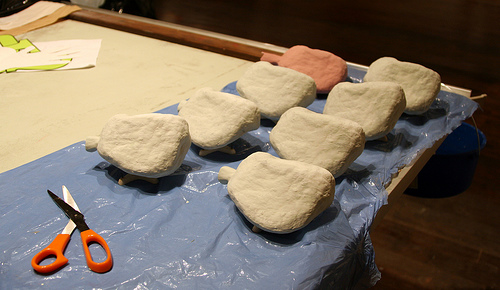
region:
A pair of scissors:
[21, 145, 102, 273]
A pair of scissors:
[80, 190, 155, 272]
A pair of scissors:
[55, 167, 126, 281]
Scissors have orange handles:
[26, 228, 120, 275]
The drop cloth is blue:
[1, 57, 478, 287]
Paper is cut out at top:
[0, 31, 100, 72]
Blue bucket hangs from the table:
[401, 116, 483, 210]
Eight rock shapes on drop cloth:
[76, 46, 445, 238]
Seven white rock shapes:
[78, 42, 445, 241]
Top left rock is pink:
[261, 38, 353, 100]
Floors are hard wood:
[129, 3, 498, 289]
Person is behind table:
[1, 0, 186, 48]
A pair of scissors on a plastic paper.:
[6, 176, 138, 288]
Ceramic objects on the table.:
[105, 93, 359, 225]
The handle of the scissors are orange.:
[18, 238, 120, 289]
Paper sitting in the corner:
[13, 31, 122, 94]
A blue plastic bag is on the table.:
[48, 141, 274, 288]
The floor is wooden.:
[393, 218, 497, 286]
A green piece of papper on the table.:
[1, 27, 73, 103]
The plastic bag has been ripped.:
[346, 101, 447, 268]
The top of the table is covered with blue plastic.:
[103, 133, 378, 283]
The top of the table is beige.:
[17, 51, 183, 125]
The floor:
[418, 206, 462, 266]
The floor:
[380, 202, 433, 257]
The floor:
[441, 207, 456, 234]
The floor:
[418, 218, 445, 265]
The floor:
[433, 181, 478, 256]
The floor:
[444, 229, 479, 286]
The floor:
[418, 229, 458, 279]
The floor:
[451, 213, 471, 273]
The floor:
[436, 194, 496, 239]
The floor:
[474, 177, 499, 246]